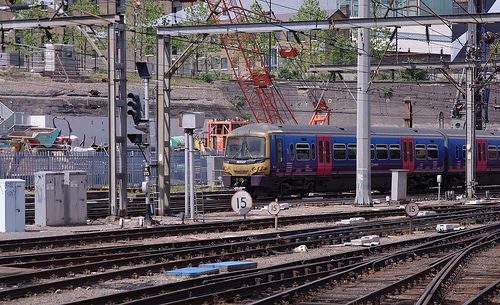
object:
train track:
[4, 199, 499, 302]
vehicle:
[202, 3, 332, 155]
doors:
[308, 131, 338, 177]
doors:
[400, 129, 420, 171]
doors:
[475, 136, 487, 175]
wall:
[347, 16, 455, 61]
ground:
[406, 192, 429, 218]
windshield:
[224, 135, 265, 159]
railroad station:
[3, 3, 493, 300]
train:
[221, 125, 496, 196]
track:
[26, 182, 498, 222]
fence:
[85, 147, 111, 189]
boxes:
[0, 175, 30, 232]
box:
[60, 167, 89, 225]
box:
[31, 170, 66, 225]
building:
[334, 2, 485, 81]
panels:
[172, 255, 261, 283]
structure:
[2, 10, 498, 234]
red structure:
[207, 12, 341, 114]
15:
[233, 195, 247, 211]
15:
[267, 204, 277, 216]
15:
[406, 204, 416, 218]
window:
[293, 140, 313, 167]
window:
[333, 144, 347, 165]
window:
[349, 144, 358, 164]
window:
[373, 142, 391, 167]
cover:
[169, 269, 210, 275]